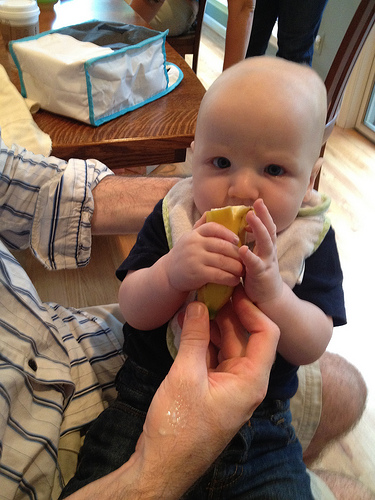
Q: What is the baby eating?
A: Banana.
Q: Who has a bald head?
A: The baby.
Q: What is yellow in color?
A: Banana.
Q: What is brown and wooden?
A: Table.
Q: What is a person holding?
A: Baby.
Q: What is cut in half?
A: A banana.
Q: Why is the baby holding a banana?
A: To eat.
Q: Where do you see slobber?
A: The man's hand.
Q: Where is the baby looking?
A: Into the camera.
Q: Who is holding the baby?
A: Man in striped shirt.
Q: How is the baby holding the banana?
A: With both hands.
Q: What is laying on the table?
A: Diaper bag.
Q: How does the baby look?
A: Serious.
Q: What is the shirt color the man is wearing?
A: Blue and white striped.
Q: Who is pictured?
A: Man holding baby on lap.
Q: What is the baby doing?
A: Eating.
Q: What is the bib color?
A: White and Green.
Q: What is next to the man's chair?
A: A table.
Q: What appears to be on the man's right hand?
A: Liquid.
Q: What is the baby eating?
A: Banana.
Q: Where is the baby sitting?
A: Lap.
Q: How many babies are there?
A: One.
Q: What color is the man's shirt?
A: White and black striped.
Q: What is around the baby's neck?
A: Bib.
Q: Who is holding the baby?
A: Man.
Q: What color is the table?
A: Brown.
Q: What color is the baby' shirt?
A: Black.